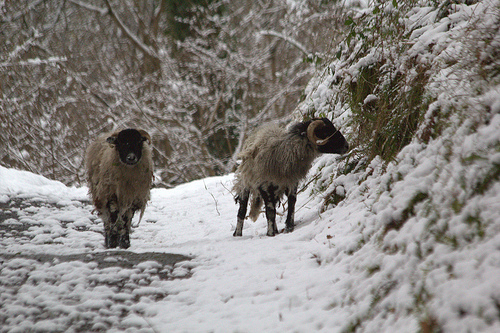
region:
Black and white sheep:
[51, 102, 175, 273]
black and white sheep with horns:
[218, 98, 360, 255]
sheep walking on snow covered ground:
[45, 93, 220, 330]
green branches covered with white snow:
[277, 14, 449, 113]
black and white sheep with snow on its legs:
[207, 106, 365, 258]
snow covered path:
[4, 176, 93, 325]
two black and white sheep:
[64, 68, 354, 265]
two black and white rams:
[65, 60, 360, 277]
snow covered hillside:
[222, 12, 481, 305]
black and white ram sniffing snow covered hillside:
[207, 71, 417, 268]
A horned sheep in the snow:
[53, 115, 195, 260]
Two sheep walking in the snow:
[28, 96, 453, 328]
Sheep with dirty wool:
[74, 125, 191, 265]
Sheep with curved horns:
[224, 70, 393, 275]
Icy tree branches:
[78, 11, 265, 126]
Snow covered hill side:
[360, 49, 497, 279]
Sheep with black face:
[297, 99, 359, 167]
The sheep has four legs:
[53, 35, 198, 282]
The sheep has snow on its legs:
[225, 114, 370, 299]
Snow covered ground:
[24, 227, 284, 328]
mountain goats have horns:
[85, 117, 353, 251]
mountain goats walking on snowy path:
[2, 116, 346, 332]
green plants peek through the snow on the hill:
[279, 0, 499, 332]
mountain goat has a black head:
[231, 114, 352, 239]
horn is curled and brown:
[305, 117, 337, 145]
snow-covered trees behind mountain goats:
[1, 2, 348, 246]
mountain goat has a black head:
[81, 125, 156, 250]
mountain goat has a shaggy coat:
[234, 117, 347, 237]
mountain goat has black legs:
[231, 118, 352, 237]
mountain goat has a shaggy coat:
[84, 126, 156, 251]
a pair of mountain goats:
[78, 104, 353, 256]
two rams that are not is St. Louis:
[81, 104, 351, 255]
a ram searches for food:
[231, 113, 361, 237]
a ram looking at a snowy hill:
[225, 108, 348, 248]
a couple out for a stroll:
[75, 110, 351, 250]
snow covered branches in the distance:
[0, 8, 299, 142]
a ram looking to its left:
[225, 98, 365, 248]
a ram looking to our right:
[225, 103, 365, 248]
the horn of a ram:
[304, 115, 334, 147]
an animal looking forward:
[75, 116, 167, 266]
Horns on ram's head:
[278, 117, 371, 184]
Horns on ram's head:
[74, 127, 184, 166]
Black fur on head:
[86, 117, 182, 189]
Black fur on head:
[296, 105, 383, 204]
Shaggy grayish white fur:
[224, 125, 335, 142]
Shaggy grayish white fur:
[62, 127, 185, 236]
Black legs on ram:
[227, 175, 382, 297]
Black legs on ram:
[68, 210, 200, 296]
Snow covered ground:
[65, 186, 176, 292]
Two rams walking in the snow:
[67, 113, 374, 260]